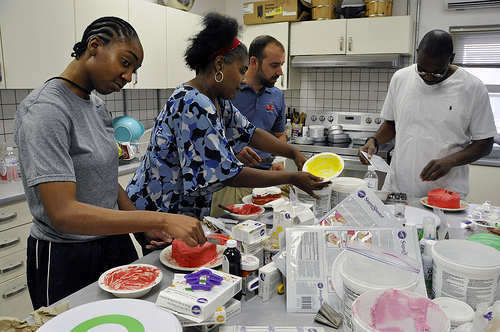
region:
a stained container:
[383, 305, 419, 329]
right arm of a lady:
[91, 206, 133, 222]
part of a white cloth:
[396, 95, 446, 148]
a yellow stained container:
[314, 155, 331, 175]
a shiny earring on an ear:
[213, 70, 226, 84]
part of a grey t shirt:
[73, 135, 107, 172]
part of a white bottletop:
[225, 238, 235, 246]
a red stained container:
[123, 265, 144, 282]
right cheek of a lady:
[101, 60, 117, 77]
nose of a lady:
[122, 67, 133, 79]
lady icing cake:
[0, 12, 187, 303]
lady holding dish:
[115, 5, 367, 224]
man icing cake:
[237, 20, 320, 210]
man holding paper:
[342, 12, 498, 226]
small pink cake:
[415, 159, 482, 224]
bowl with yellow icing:
[277, 120, 377, 212]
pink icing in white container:
[329, 259, 478, 330]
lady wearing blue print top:
[149, 38, 314, 221]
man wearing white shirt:
[357, 13, 498, 213]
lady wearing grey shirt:
[1, 8, 206, 251]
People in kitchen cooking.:
[21, 5, 327, 292]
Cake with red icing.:
[164, 227, 246, 272]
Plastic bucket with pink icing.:
[346, 285, 453, 330]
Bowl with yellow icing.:
[299, 144, 351, 186]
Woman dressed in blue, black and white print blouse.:
[128, 93, 263, 223]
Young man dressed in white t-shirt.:
[377, 61, 497, 191]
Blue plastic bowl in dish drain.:
[112, 110, 154, 150]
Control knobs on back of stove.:
[306, 108, 383, 129]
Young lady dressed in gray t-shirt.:
[12, 79, 128, 243]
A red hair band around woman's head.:
[208, 27, 245, 67]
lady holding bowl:
[120, 12, 362, 240]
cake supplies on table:
[162, 155, 498, 319]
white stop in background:
[292, 98, 419, 175]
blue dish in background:
[107, 112, 154, 154]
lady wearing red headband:
[167, 21, 264, 114]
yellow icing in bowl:
[282, 140, 367, 207]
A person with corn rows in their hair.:
[64, 13, 146, 100]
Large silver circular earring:
[214, 70, 225, 83]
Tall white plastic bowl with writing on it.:
[432, 236, 499, 303]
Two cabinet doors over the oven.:
[286, 14, 415, 56]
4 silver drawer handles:
[2, 210, 24, 302]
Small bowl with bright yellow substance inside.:
[302, 150, 344, 184]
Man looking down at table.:
[358, 24, 494, 203]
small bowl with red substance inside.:
[95, 263, 164, 298]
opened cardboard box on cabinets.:
[242, 0, 310, 23]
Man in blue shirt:
[210, 35, 288, 222]